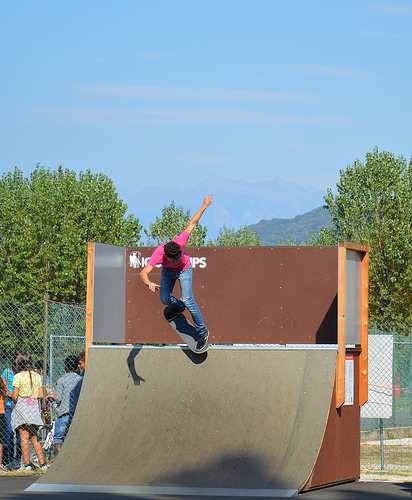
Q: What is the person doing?
A: Skateboarding.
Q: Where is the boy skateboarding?
A: On a ramp.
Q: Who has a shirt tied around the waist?
A: The girl in the yellow shirt.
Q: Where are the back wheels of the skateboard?
A: In the air.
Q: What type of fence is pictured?
A: Chain link.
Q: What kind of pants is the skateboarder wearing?
A: Jeans.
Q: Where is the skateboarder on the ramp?
A: At the top.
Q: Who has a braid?
A: The girl in the yellow shirt.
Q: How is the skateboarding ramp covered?
A: Paved.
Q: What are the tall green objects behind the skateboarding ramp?
A: Trees.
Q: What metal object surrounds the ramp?
A: Gate.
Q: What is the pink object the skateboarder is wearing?
A: Shirt.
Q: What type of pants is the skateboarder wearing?
A: Long pants.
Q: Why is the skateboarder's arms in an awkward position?
A: For balance.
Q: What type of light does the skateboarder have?
A: Daylight.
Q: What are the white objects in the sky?
A: Clouds.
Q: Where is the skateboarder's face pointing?
A: Downward.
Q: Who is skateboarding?
A: A man.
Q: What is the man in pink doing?
A: Skateboarding.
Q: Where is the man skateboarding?
A: In a skate park.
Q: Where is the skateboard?
A: On a ramp.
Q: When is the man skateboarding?
A: During daylight hours.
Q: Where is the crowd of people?
A: Behind the fence.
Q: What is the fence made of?
A: Metal.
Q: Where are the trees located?
A: Behind the group of people.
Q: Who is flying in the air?
A: A skateboarder.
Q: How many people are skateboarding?
A: One.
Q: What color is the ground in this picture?
A: Black.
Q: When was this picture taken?
A: Daytime.